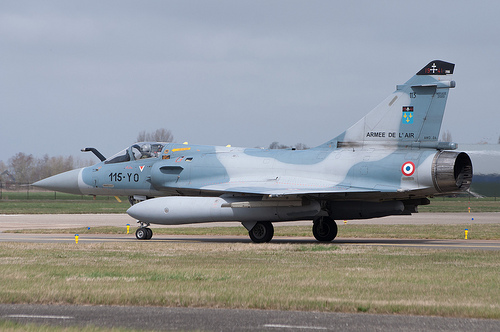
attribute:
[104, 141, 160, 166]
cockpit — plane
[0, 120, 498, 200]
trees — leafless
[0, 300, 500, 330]
paved road — grey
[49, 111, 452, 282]
missle — large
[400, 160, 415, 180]
logo — red, white, and blue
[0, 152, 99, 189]
trees — green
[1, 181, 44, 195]
fence — chain link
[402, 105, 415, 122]
logo — blue and yellow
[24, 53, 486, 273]
blue jet — blue and white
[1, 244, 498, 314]
grass — green